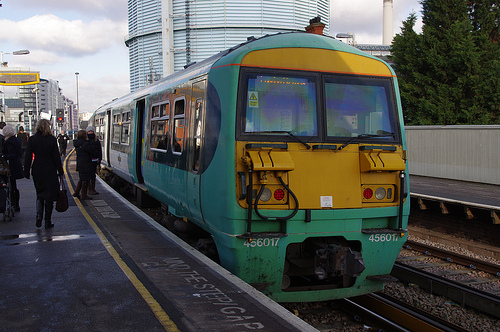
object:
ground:
[412, 172, 500, 211]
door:
[135, 100, 145, 187]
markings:
[139, 257, 168, 268]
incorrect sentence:
[163, 257, 208, 284]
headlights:
[274, 189, 285, 200]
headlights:
[363, 188, 373, 199]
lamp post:
[74, 72, 80, 133]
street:
[2, 138, 164, 332]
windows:
[148, 95, 183, 154]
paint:
[136, 257, 266, 330]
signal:
[56, 108, 64, 127]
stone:
[384, 276, 500, 331]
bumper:
[238, 215, 410, 303]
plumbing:
[394, 259, 500, 319]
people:
[23, 119, 64, 230]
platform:
[0, 182, 324, 332]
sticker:
[248, 91, 259, 108]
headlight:
[257, 188, 272, 202]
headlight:
[374, 187, 387, 201]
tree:
[388, 0, 499, 128]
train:
[87, 16, 412, 304]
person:
[73, 130, 99, 200]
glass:
[245, 73, 400, 141]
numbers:
[243, 238, 281, 248]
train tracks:
[344, 239, 498, 332]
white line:
[97, 177, 323, 331]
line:
[62, 145, 181, 331]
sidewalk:
[0, 140, 324, 332]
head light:
[360, 183, 397, 202]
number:
[368, 233, 400, 242]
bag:
[55, 177, 69, 213]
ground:
[0, 146, 322, 331]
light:
[250, 184, 289, 205]